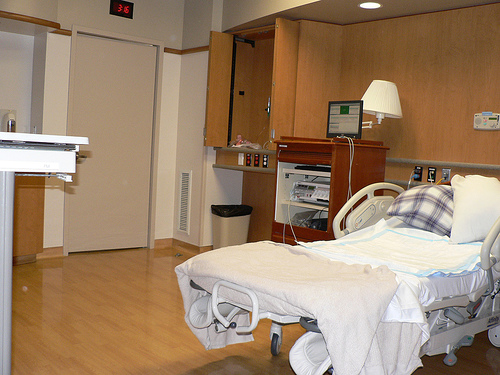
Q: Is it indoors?
A: Yes, it is indoors.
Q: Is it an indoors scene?
A: Yes, it is indoors.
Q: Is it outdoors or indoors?
A: It is indoors.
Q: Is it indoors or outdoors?
A: It is indoors.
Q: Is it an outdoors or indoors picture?
A: It is indoors.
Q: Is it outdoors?
A: No, it is indoors.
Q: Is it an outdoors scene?
A: No, it is indoors.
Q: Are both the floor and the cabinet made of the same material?
A: Yes, both the floor and the cabinet are made of wood.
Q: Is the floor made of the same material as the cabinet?
A: Yes, both the floor and the cabinet are made of wood.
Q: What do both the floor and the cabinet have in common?
A: The material, both the floor and the cabinet are wooden.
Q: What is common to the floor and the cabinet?
A: The material, both the floor and the cabinet are wooden.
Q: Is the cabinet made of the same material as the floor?
A: Yes, both the cabinet and the floor are made of wood.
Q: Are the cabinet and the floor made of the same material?
A: Yes, both the cabinet and the floor are made of wood.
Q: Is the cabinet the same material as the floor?
A: Yes, both the cabinet and the floor are made of wood.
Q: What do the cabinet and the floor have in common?
A: The material, both the cabinet and the floor are wooden.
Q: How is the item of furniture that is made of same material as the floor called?
A: The piece of furniture is a cabinet.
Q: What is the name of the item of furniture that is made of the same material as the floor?
A: The piece of furniture is a cabinet.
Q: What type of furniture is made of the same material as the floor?
A: The cabinet is made of the same material as the floor.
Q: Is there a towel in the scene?
A: No, there are no towels.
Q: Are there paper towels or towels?
A: No, there are no towels or paper towels.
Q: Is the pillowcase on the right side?
A: Yes, the pillowcase is on the right of the image.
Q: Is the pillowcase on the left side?
A: No, the pillowcase is on the right of the image.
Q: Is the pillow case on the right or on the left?
A: The pillow case is on the right of the image.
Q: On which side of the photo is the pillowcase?
A: The pillowcase is on the right of the image.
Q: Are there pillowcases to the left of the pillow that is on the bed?
A: Yes, there is a pillowcase to the left of the pillow.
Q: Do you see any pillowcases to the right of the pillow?
A: No, the pillowcase is to the left of the pillow.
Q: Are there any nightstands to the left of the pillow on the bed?
A: No, there is a pillowcase to the left of the pillow.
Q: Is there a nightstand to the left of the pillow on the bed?
A: No, there is a pillowcase to the left of the pillow.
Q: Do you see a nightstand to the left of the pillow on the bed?
A: No, there is a pillowcase to the left of the pillow.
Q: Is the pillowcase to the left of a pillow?
A: Yes, the pillowcase is to the left of a pillow.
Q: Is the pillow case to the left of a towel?
A: No, the pillow case is to the left of a pillow.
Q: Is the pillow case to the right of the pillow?
A: No, the pillow case is to the left of the pillow.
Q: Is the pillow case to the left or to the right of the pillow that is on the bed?
A: The pillow case is to the left of the pillow.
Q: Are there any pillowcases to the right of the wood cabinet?
A: Yes, there is a pillowcase to the right of the cabinet.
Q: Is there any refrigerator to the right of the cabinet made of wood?
A: No, there is a pillowcase to the right of the cabinet.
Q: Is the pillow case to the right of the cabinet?
A: Yes, the pillow case is to the right of the cabinet.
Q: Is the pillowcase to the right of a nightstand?
A: No, the pillowcase is to the right of the cabinet.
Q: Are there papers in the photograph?
A: No, there are no papers.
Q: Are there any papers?
A: No, there are no papers.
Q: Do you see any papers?
A: No, there are no papers.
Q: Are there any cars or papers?
A: No, there are no papers or cars.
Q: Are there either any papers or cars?
A: No, there are no papers or cars.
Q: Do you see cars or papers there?
A: No, there are no papers or cars.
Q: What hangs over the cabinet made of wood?
A: The wires hang over the cabinet.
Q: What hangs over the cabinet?
A: The wires hang over the cabinet.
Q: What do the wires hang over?
A: The wires hang over the cabinet.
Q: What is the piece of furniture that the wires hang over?
A: The piece of furniture is a cabinet.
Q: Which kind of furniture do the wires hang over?
A: The wires hang over the cabinet.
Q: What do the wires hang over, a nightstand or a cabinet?
A: The wires hang over a cabinet.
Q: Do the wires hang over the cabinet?
A: Yes, the wires hang over the cabinet.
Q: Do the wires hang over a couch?
A: No, the wires hang over the cabinet.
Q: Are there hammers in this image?
A: No, there are no hammers.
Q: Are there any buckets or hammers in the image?
A: No, there are no hammers or buckets.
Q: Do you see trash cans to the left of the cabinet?
A: Yes, there is a trash can to the left of the cabinet.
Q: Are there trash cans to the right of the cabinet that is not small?
A: No, the trash can is to the left of the cabinet.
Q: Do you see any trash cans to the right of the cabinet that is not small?
A: No, the trash can is to the left of the cabinet.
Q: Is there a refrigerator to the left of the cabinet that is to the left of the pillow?
A: No, there is a trash can to the left of the cabinet.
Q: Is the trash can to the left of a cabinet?
A: Yes, the trash can is to the left of a cabinet.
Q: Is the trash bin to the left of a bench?
A: No, the trash bin is to the left of a cabinet.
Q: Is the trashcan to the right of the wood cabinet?
A: No, the trashcan is to the left of the cabinet.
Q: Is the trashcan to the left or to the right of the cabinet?
A: The trashcan is to the left of the cabinet.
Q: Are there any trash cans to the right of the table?
A: Yes, there is a trash can to the right of the table.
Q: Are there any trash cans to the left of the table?
A: No, the trash can is to the right of the table.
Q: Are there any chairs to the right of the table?
A: No, there is a trash can to the right of the table.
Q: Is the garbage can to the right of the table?
A: Yes, the garbage can is to the right of the table.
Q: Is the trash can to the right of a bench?
A: No, the trash can is to the right of the table.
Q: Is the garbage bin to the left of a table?
A: No, the garbage bin is to the right of a table.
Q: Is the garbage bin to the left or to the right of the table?
A: The garbage bin is to the right of the table.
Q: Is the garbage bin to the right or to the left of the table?
A: The garbage bin is to the right of the table.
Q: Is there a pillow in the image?
A: Yes, there is a pillow.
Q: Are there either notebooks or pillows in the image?
A: Yes, there is a pillow.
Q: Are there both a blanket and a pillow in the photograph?
A: Yes, there are both a pillow and a blanket.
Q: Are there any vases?
A: No, there are no vases.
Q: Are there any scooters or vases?
A: No, there are no vases or scooters.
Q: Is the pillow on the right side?
A: Yes, the pillow is on the right of the image.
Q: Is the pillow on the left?
A: No, the pillow is on the right of the image.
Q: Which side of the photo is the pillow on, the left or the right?
A: The pillow is on the right of the image.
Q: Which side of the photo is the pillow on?
A: The pillow is on the right of the image.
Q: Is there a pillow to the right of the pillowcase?
A: Yes, there is a pillow to the right of the pillowcase.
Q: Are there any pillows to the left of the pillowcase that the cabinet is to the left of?
A: No, the pillow is to the right of the pillowcase.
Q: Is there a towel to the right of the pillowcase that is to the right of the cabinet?
A: No, there is a pillow to the right of the pillow case.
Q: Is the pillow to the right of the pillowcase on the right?
A: Yes, the pillow is to the right of the pillowcase.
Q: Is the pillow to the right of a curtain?
A: No, the pillow is to the right of the pillowcase.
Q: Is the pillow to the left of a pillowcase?
A: No, the pillow is to the right of a pillowcase.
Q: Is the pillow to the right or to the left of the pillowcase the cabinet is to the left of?
A: The pillow is to the right of the pillowcase.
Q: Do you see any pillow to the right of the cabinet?
A: Yes, there is a pillow to the right of the cabinet.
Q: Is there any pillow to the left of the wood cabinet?
A: No, the pillow is to the right of the cabinet.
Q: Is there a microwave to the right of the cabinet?
A: No, there is a pillow to the right of the cabinet.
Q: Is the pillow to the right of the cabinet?
A: Yes, the pillow is to the right of the cabinet.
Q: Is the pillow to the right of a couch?
A: No, the pillow is to the right of the cabinet.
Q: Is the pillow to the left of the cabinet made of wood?
A: No, the pillow is to the right of the cabinet.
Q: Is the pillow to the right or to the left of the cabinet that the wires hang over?
A: The pillow is to the right of the cabinet.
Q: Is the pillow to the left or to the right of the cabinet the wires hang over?
A: The pillow is to the right of the cabinet.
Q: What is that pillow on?
A: The pillow is on the bed.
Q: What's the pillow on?
A: The pillow is on the bed.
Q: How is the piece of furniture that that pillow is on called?
A: The piece of furniture is a bed.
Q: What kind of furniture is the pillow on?
A: The pillow is on the bed.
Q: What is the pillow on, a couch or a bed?
A: The pillow is on a bed.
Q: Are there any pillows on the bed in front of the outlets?
A: Yes, there is a pillow on the bed.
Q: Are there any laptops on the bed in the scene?
A: No, there is a pillow on the bed.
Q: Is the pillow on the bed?
A: Yes, the pillow is on the bed.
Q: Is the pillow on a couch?
A: No, the pillow is on the bed.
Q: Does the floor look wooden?
A: Yes, the floor is wooden.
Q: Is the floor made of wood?
A: Yes, the floor is made of wood.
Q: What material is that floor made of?
A: The floor is made of wood.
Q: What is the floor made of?
A: The floor is made of wood.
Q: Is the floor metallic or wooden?
A: The floor is wooden.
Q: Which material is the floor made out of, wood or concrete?
A: The floor is made of wood.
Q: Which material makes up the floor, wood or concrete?
A: The floor is made of wood.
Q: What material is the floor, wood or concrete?
A: The floor is made of wood.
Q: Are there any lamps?
A: Yes, there is a lamp.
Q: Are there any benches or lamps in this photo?
A: Yes, there is a lamp.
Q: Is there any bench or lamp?
A: Yes, there is a lamp.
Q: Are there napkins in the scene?
A: No, there are no napkins.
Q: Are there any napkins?
A: No, there are no napkins.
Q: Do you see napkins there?
A: No, there are no napkins.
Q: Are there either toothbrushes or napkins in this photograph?
A: No, there are no napkins or toothbrushes.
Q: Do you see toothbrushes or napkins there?
A: No, there are no napkins or toothbrushes.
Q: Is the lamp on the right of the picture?
A: Yes, the lamp is on the right of the image.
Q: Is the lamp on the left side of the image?
A: No, the lamp is on the right of the image.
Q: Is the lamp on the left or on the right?
A: The lamp is on the right of the image.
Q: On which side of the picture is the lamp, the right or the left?
A: The lamp is on the right of the image.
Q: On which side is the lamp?
A: The lamp is on the right of the image.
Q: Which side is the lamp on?
A: The lamp is on the right of the image.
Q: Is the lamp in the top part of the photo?
A: Yes, the lamp is in the top of the image.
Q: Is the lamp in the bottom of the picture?
A: No, the lamp is in the top of the image.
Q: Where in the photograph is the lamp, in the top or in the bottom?
A: The lamp is in the top of the image.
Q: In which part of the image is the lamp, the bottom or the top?
A: The lamp is in the top of the image.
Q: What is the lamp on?
A: The lamp is on the wall.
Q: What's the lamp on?
A: The lamp is on the wall.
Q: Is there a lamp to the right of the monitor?
A: Yes, there is a lamp to the right of the monitor.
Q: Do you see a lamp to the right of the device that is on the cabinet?
A: Yes, there is a lamp to the right of the monitor.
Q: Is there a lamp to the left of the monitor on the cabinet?
A: No, the lamp is to the right of the monitor.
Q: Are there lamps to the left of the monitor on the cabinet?
A: No, the lamp is to the right of the monitor.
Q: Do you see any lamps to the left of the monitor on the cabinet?
A: No, the lamp is to the right of the monitor.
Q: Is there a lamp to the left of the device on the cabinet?
A: No, the lamp is to the right of the monitor.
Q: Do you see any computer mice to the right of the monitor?
A: No, there is a lamp to the right of the monitor.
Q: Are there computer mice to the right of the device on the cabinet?
A: No, there is a lamp to the right of the monitor.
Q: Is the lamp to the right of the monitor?
A: Yes, the lamp is to the right of the monitor.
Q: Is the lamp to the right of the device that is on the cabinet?
A: Yes, the lamp is to the right of the monitor.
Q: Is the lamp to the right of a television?
A: No, the lamp is to the right of the monitor.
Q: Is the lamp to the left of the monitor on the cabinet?
A: No, the lamp is to the right of the monitor.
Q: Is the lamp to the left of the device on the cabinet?
A: No, the lamp is to the right of the monitor.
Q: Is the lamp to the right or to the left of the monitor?
A: The lamp is to the right of the monitor.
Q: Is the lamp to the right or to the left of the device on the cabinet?
A: The lamp is to the right of the monitor.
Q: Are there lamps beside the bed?
A: Yes, there is a lamp beside the bed.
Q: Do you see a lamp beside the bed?
A: Yes, there is a lamp beside the bed.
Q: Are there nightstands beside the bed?
A: No, there is a lamp beside the bed.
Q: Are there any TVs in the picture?
A: No, there are no tvs.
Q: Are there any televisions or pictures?
A: No, there are no televisions or pictures.